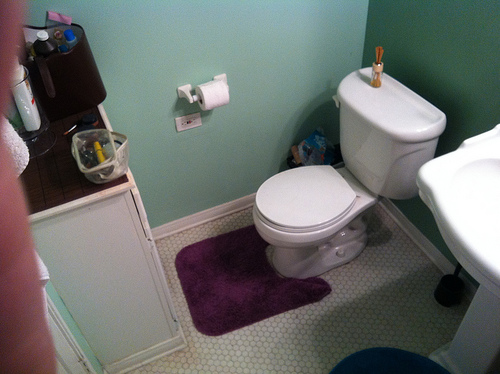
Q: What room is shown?
A: It is a bathroom.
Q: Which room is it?
A: It is a bathroom.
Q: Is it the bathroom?
A: Yes, it is the bathroom.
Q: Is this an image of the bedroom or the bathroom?
A: It is showing the bathroom.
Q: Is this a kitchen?
A: No, it is a bathroom.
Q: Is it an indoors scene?
A: Yes, it is indoors.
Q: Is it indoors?
A: Yes, it is indoors.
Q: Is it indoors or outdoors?
A: It is indoors.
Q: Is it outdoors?
A: No, it is indoors.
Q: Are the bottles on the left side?
A: Yes, the bottles are on the left of the image.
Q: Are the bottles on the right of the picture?
A: No, the bottles are on the left of the image.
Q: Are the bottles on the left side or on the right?
A: The bottles are on the left of the image.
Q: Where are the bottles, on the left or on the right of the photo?
A: The bottles are on the left of the image.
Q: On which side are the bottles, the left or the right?
A: The bottles are on the left of the image.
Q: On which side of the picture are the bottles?
A: The bottles are on the left of the image.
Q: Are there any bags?
A: Yes, there is a bag.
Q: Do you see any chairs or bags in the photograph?
A: Yes, there is a bag.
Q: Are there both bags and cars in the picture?
A: No, there is a bag but no cars.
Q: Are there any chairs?
A: No, there are no chairs.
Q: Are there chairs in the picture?
A: No, there are no chairs.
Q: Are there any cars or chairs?
A: No, there are no chairs or cars.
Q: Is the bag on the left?
A: Yes, the bag is on the left of the image.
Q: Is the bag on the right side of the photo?
A: No, the bag is on the left of the image.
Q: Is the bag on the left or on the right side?
A: The bag is on the left of the image.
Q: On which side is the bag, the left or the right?
A: The bag is on the left of the image.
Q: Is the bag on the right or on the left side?
A: The bag is on the left of the image.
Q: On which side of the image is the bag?
A: The bag is on the left of the image.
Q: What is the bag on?
A: The bag is on the counter.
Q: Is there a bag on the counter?
A: Yes, there is a bag on the counter.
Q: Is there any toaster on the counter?
A: No, there is a bag on the counter.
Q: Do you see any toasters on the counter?
A: No, there is a bag on the counter.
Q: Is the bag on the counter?
A: Yes, the bag is on the counter.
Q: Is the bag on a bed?
A: No, the bag is on the counter.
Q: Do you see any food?
A: No, there is no food.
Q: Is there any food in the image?
A: No, there is no food.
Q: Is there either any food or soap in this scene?
A: No, there are no food or soaps.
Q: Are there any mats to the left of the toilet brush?
A: Yes, there is a mat to the left of the toilet brush.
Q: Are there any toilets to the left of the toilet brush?
A: No, there is a mat to the left of the toilet brush.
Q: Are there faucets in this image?
A: No, there are no faucets.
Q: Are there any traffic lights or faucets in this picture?
A: No, there are no faucets or traffic lights.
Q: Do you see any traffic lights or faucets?
A: No, there are no faucets or traffic lights.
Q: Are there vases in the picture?
A: No, there are no vases.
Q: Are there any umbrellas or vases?
A: No, there are no vases or umbrellas.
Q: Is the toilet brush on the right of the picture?
A: Yes, the toilet brush is on the right of the image.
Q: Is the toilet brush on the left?
A: No, the toilet brush is on the right of the image.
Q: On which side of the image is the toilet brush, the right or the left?
A: The toilet brush is on the right of the image.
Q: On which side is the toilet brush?
A: The toilet brush is on the right of the image.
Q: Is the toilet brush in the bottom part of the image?
A: Yes, the toilet brush is in the bottom of the image.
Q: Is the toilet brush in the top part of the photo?
A: No, the toilet brush is in the bottom of the image.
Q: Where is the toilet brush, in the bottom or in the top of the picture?
A: The toilet brush is in the bottom of the image.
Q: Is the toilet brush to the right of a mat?
A: Yes, the toilet brush is to the right of a mat.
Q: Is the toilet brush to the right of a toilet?
A: No, the toilet brush is to the right of a mat.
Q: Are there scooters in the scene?
A: No, there are no scooters.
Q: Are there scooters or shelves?
A: No, there are no scooters or shelves.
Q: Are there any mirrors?
A: No, there are no mirrors.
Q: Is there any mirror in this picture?
A: No, there are no mirrors.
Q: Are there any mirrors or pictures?
A: No, there are no mirrors or pictures.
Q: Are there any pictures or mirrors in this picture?
A: No, there are no mirrors or pictures.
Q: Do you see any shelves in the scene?
A: No, there are no shelves.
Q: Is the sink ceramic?
A: Yes, the sink is ceramic.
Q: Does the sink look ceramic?
A: Yes, the sink is ceramic.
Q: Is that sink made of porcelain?
A: Yes, the sink is made of porcelain.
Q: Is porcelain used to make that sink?
A: Yes, the sink is made of porcelain.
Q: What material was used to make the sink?
A: The sink is made of porcelain.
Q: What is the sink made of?
A: The sink is made of porcelain.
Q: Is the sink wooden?
A: No, the sink is ceramic.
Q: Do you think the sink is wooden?
A: No, the sink is ceramic.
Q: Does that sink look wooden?
A: No, the sink is ceramic.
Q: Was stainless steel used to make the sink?
A: No, the sink is made of porcelain.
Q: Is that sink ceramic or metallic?
A: The sink is ceramic.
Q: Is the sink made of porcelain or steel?
A: The sink is made of porcelain.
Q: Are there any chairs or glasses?
A: No, there are no chairs or glasses.